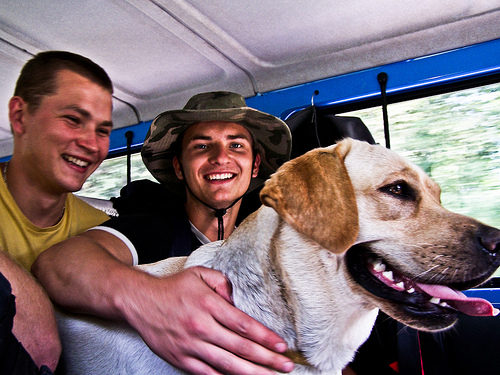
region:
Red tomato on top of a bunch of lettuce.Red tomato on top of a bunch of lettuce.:
[480, 305, 490, 316]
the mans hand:
[131, 268, 304, 366]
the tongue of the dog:
[431, 291, 491, 315]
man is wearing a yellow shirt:
[1, 221, 31, 246]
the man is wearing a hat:
[186, 88, 246, 117]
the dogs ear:
[275, 168, 344, 213]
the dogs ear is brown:
[277, 167, 335, 212]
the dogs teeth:
[376, 260, 393, 282]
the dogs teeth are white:
[371, 260, 391, 282]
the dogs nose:
[479, 230, 497, 250]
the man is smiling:
[206, 173, 238, 183]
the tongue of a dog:
[421, 285, 499, 317]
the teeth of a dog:
[374, 263, 397, 280]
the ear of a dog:
[276, 162, 360, 249]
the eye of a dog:
[376, 179, 414, 199]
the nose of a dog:
[473, 219, 499, 259]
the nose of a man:
[78, 133, 105, 153]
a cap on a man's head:
[165, 90, 274, 126]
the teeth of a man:
[205, 169, 235, 181]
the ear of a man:
[252, 154, 262, 176]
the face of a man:
[191, 124, 246, 199]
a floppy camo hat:
[136, 88, 298, 181]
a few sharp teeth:
[366, 253, 409, 292]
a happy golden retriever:
[41, 140, 493, 362]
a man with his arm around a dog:
[79, 83, 499, 370]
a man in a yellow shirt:
[1, 46, 115, 369]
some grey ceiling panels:
[27, 2, 374, 108]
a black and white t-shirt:
[96, 203, 265, 262]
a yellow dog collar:
[258, 344, 331, 370]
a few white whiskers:
[373, 229, 473, 296]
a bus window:
[336, 85, 494, 300]